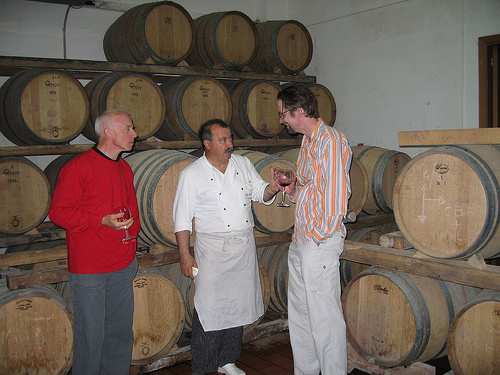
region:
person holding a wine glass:
[36, 100, 143, 372]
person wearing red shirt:
[40, 112, 165, 374]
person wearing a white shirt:
[152, 98, 274, 370]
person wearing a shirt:
[260, 78, 361, 372]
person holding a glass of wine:
[265, 85, 363, 371]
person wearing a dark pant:
[40, 92, 157, 374]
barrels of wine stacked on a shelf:
[5, 38, 343, 148]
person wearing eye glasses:
[253, 81, 379, 373]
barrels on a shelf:
[352, 133, 493, 293]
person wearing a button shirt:
[162, 103, 279, 373]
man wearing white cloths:
[163, 115, 295, 369]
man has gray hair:
[61, 103, 151, 208]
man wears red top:
[43, 101, 156, 371]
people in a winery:
[3, 3, 496, 370]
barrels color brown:
[95, 0, 320, 78]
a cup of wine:
[270, 161, 295, 211]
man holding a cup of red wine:
[164, 113, 302, 239]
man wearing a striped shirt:
[263, 78, 370, 374]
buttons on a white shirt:
[203, 167, 256, 236]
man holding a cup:
[46, 105, 159, 297]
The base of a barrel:
[155, 13, 182, 52]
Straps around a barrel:
[195, 26, 207, 33]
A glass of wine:
[279, 175, 289, 183]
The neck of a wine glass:
[282, 192, 284, 204]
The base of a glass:
[276, 204, 290, 206]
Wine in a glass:
[280, 183, 288, 186]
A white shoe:
[229, 367, 236, 374]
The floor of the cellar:
[259, 361, 285, 373]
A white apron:
[215, 272, 251, 319]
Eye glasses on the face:
[280, 112, 284, 118]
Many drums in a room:
[0, 2, 499, 374]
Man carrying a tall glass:
[270, 75, 358, 372]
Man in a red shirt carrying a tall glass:
[45, 102, 142, 374]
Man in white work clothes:
[167, 113, 280, 373]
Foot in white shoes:
[213, 359, 249, 374]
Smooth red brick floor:
[131, 338, 301, 373]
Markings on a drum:
[196, 81, 211, 99]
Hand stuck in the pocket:
[288, 213, 347, 251]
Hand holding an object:
[178, 251, 205, 284]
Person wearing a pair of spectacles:
[272, 80, 336, 137]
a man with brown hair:
[270, 85, 320, 135]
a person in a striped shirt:
[295, 130, 355, 235]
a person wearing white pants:
[290, 235, 341, 370]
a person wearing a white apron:
[187, 221, 262, 326]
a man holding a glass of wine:
[272, 85, 359, 210]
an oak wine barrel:
[98, 2, 194, 60]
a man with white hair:
[90, 106, 146, 152]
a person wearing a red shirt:
[45, 141, 137, 271]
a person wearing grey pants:
[65, 261, 135, 367]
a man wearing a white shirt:
[185, 120, 265, 231]